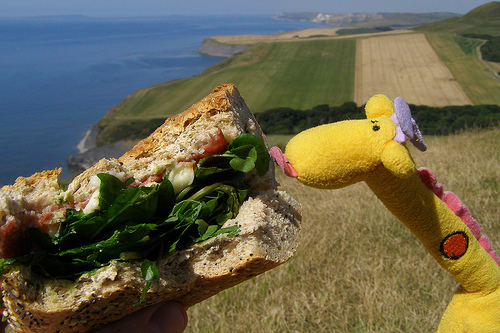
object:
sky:
[1, 0, 476, 25]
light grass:
[314, 239, 418, 309]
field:
[177, 198, 430, 331]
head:
[269, 94, 429, 190]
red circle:
[442, 232, 468, 258]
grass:
[293, 41, 345, 104]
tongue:
[270, 146, 299, 178]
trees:
[104, 101, 498, 140]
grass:
[184, 126, 500, 333]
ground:
[166, 126, 500, 333]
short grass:
[112, 35, 500, 121]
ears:
[380, 140, 418, 180]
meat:
[0, 128, 227, 258]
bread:
[0, 82, 303, 333]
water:
[0, 0, 306, 186]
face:
[268, 115, 396, 190]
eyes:
[370, 118, 380, 132]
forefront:
[3, 76, 499, 328]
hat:
[393, 96, 428, 152]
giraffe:
[266, 93, 500, 332]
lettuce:
[0, 132, 272, 304]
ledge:
[123, 32, 193, 64]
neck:
[363, 170, 499, 294]